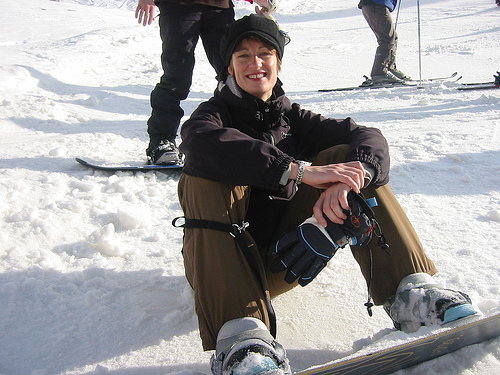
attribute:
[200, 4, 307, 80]
hat — black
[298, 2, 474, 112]
person — skiing, standing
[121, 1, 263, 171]
pants — black, dark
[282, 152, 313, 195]
watch — silver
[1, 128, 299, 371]
snow — white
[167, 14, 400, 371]
woman — smiling, sitting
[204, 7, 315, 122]
cap — black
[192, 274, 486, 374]
boots — attached, blue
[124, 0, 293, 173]
person — standing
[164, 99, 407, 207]
sleeve — elastic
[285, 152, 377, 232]
fingers — white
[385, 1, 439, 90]
poles — skinny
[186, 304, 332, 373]
boot — ski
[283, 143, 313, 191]
bracelet — silver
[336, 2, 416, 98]
pants — tan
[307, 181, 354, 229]
hand — woman's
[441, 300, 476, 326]
tip — blue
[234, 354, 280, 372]
tip — blue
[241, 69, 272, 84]
grin — wide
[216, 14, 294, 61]
cap — black